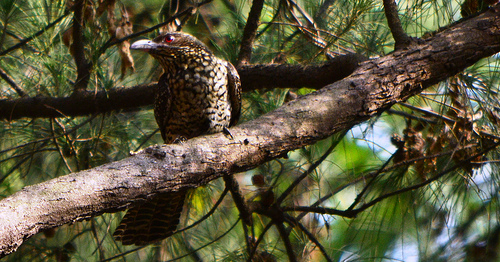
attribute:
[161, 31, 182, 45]
eye — red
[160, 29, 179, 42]
eyes — bright red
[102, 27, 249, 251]
bird — speckled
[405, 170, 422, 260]
pine needle — green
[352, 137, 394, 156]
pine needle — green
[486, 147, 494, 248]
pine needle — green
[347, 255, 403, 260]
pine needle — green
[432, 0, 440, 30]
pine needle — green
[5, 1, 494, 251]
tree — pine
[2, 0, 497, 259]
branch — brown